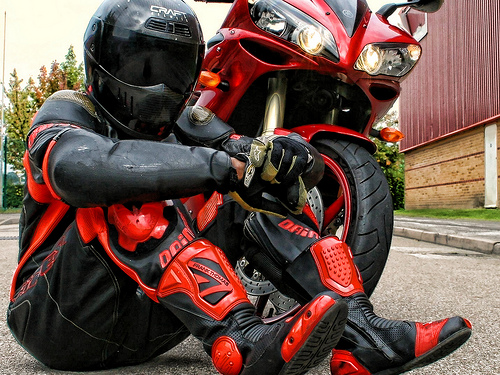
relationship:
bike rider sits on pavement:
[7, 3, 472, 374] [1, 214, 500, 373]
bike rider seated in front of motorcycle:
[7, 3, 472, 374] [187, 0, 445, 321]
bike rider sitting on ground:
[7, 3, 472, 374] [1, 214, 500, 373]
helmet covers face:
[82, 0, 204, 142] [95, 24, 192, 120]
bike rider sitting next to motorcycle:
[7, 3, 472, 374] [187, 0, 445, 321]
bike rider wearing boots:
[7, 3, 472, 374] [154, 239, 345, 374]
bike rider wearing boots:
[7, 3, 472, 374] [280, 232, 472, 373]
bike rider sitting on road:
[7, 3, 472, 374] [1, 214, 500, 373]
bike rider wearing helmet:
[7, 3, 472, 374] [82, 0, 204, 142]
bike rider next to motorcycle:
[7, 3, 472, 374] [187, 0, 445, 321]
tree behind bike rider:
[0, 66, 36, 174] [7, 3, 472, 374]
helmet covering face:
[82, 0, 204, 142] [95, 24, 192, 120]